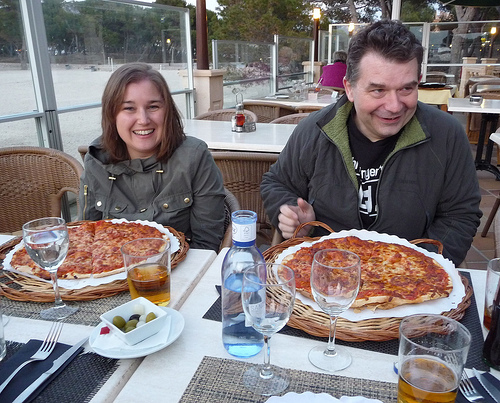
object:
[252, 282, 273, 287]
edge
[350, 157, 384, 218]
design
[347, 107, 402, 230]
black shirt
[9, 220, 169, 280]
pizza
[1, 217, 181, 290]
basket tray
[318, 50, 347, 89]
person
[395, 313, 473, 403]
glass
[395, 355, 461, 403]
beer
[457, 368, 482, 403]
silverware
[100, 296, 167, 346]
bowl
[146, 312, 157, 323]
olives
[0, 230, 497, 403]
table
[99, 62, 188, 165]
hair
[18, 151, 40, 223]
wicker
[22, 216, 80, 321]
boys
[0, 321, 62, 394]
fork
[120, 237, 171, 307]
glass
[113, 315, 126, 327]
olive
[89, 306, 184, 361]
dish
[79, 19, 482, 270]
couple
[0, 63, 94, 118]
snow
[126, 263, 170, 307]
beer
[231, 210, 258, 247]
bottle neck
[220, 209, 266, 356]
bottle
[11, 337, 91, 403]
fork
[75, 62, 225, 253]
girl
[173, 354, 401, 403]
placemat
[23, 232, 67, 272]
water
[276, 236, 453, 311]
pizza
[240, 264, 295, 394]
clear glass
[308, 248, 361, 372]
clear glass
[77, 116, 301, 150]
table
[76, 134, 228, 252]
jacket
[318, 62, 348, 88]
jacket